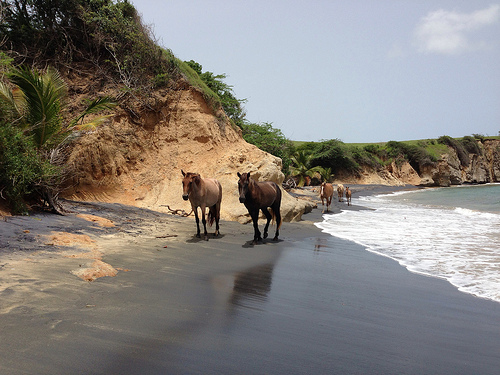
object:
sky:
[132, 1, 500, 141]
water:
[316, 184, 498, 308]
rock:
[416, 177, 434, 186]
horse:
[233, 173, 282, 246]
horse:
[319, 183, 334, 215]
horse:
[337, 184, 345, 202]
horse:
[345, 187, 353, 206]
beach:
[1, 184, 500, 375]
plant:
[8, 64, 64, 150]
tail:
[206, 206, 217, 230]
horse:
[179, 170, 222, 242]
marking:
[320, 186, 324, 195]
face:
[235, 172, 251, 205]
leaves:
[307, 165, 328, 174]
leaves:
[300, 151, 305, 163]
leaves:
[305, 169, 316, 180]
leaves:
[292, 160, 301, 167]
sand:
[53, 231, 118, 280]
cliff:
[6, 29, 305, 225]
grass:
[170, 56, 219, 103]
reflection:
[232, 263, 273, 300]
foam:
[313, 210, 499, 301]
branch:
[167, 206, 192, 218]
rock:
[257, 141, 286, 185]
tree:
[2, 1, 149, 50]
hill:
[287, 139, 498, 161]